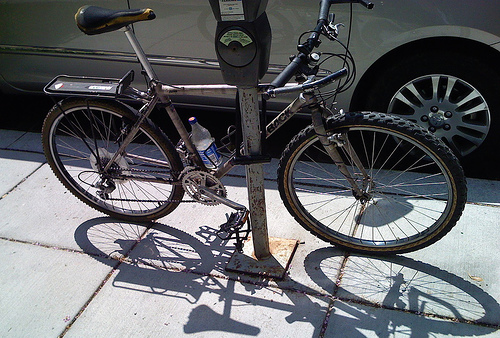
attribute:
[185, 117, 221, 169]
bottle — plastic, water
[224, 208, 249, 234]
pedal — black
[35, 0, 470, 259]
bicycle — parked, leaning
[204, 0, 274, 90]
parking meter — here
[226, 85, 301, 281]
pole — rusty, gray, metallic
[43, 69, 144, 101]
rack — rear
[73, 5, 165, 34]
seat — high, black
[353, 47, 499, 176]
wheel — black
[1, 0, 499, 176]
car — white, parked